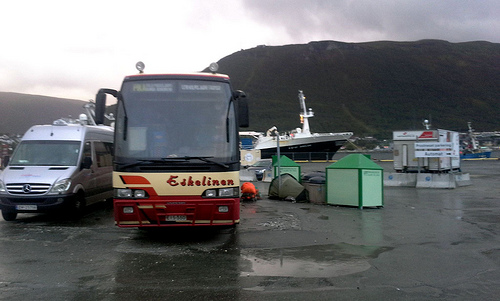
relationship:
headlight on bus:
[202, 182, 238, 197] [89, 68, 255, 230]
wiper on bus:
[177, 151, 225, 174] [73, 36, 298, 298]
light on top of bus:
[136, 60, 145, 74] [93, 60, 249, 230]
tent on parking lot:
[323, 150, 381, 211] [0, 157, 497, 299]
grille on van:
[4, 179, 50, 199] [0, 119, 117, 217]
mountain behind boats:
[207, 31, 497, 139] [242, 110, 479, 182]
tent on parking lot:
[272, 105, 423, 215] [10, 138, 496, 298]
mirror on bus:
[231, 86, 252, 127] [93, 60, 249, 230]